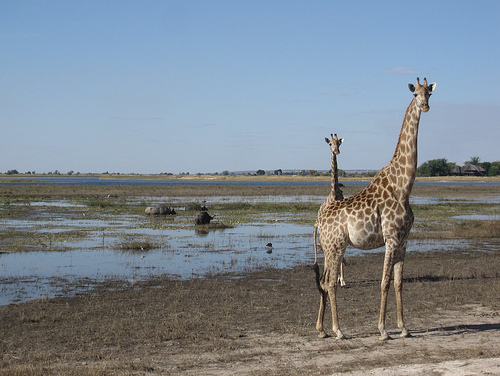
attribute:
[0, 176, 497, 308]
water — swamp-like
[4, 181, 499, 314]
marsh — grassy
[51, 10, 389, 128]
clouds — white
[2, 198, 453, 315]
water — muddy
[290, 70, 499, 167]
clouds — white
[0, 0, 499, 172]
sky — blue, clear, light blue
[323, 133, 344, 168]
head — young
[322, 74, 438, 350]
tan giraffe — brown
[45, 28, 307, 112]
sky — blue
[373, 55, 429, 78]
clouds — white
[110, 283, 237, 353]
grass — dead, grey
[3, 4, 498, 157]
sky — blue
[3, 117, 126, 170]
clouds — white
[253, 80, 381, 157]
clouds — white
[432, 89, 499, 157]
clouds — white